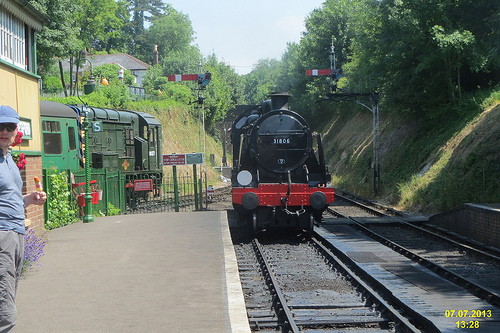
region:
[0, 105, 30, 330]
Woman standing outside a train station.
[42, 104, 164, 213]
Green train on the tracks.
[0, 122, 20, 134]
Sunglasses over the woman's eyes.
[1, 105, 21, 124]
Cap on the woman's head.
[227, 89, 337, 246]
Red and black train on the tracks.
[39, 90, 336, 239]
Two trains on tracks.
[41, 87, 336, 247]
Trains at the station.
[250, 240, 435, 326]
Railroad tracks beside the train station.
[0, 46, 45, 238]
Part of the train station.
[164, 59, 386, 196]
Railroad traffic lights on both sides of the track.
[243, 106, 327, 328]
the train is red and black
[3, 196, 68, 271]
he has a blue shirt on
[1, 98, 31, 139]
he has a blue hat on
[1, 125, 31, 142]
he has black shades on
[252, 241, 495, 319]
two sets of train tracks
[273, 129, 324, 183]
31806 written on train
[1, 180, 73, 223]
he is holding a popsicle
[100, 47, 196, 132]
a house in the background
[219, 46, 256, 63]
the sky looks cloudy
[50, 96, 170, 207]
the train is green and black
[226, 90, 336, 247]
Cool old train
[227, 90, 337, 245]
Black and red train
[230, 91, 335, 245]
Train number 31806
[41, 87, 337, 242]
Two trains and one train car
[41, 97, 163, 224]
Green train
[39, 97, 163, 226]
Green train with a green train car.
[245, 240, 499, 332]
Train tracks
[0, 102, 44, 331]
Tourist wearing a blue shirt and hat.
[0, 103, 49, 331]
Tourist eating a popsicle.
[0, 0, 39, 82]
Windows of the train station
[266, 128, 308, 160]
Number on the train.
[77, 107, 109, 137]
S on a pole.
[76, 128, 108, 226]
The pole is green.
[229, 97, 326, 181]
The train is black.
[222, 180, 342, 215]
Part of the train is red.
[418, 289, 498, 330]
Time and day on the photo.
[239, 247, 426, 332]
The train tracks are black.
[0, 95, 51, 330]
Person in the photo.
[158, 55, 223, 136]
The train tracks caution lights.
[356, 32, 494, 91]
The leaves on the trees are green.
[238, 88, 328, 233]
front of black and red train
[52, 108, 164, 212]
side of green train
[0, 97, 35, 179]
person in blue hat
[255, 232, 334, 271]
track rails under train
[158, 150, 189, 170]
red sign with white words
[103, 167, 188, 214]
green fence on edge of platform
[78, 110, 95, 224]
green pole on platform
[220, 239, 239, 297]
white line on edge of platform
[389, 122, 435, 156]
grass on shady hill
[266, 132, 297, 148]
numbers on front of train